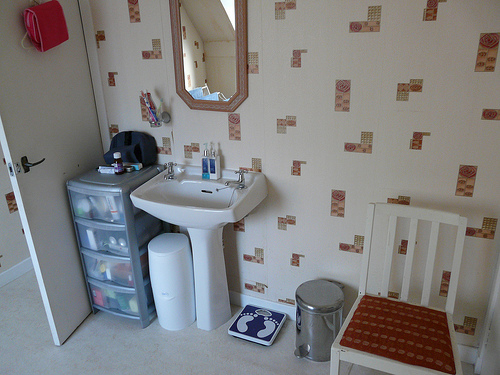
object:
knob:
[234, 168, 246, 175]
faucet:
[224, 170, 246, 191]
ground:
[109, 321, 249, 373]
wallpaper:
[298, 63, 456, 162]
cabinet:
[64, 163, 162, 328]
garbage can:
[293, 279, 345, 362]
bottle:
[209, 150, 221, 179]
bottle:
[201, 150, 210, 179]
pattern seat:
[340, 295, 458, 373]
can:
[294, 278, 344, 362]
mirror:
[166, 1, 251, 112]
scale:
[229, 300, 283, 345]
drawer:
[65, 183, 133, 224]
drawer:
[70, 216, 136, 258]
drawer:
[80, 246, 139, 293]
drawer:
[84, 276, 150, 316]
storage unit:
[55, 159, 177, 330]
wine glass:
[18, 148, 48, 179]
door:
[0, 0, 103, 350]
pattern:
[450, 162, 484, 199]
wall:
[76, 0, 497, 363]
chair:
[330, 202, 468, 375]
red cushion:
[336, 285, 459, 367]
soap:
[207, 141, 220, 180]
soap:
[199, 142, 211, 179]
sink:
[131, 161, 269, 329]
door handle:
[24, 157, 47, 170]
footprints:
[233, 311, 279, 337]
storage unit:
[23, 12, 463, 362]